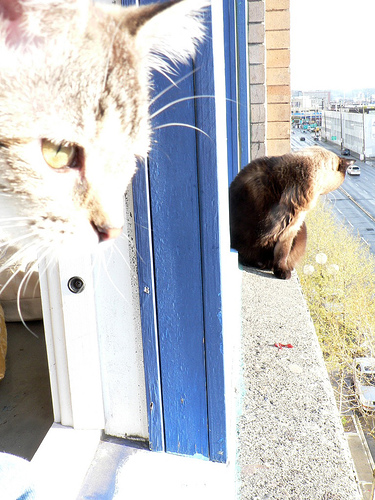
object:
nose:
[90, 216, 118, 244]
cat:
[0, 1, 213, 343]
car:
[344, 162, 361, 178]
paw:
[275, 262, 295, 282]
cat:
[244, 136, 349, 222]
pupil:
[54, 142, 64, 155]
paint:
[115, 4, 236, 459]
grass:
[293, 195, 373, 389]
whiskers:
[2, 214, 60, 328]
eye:
[2, 0, 239, 343]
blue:
[163, 304, 199, 345]